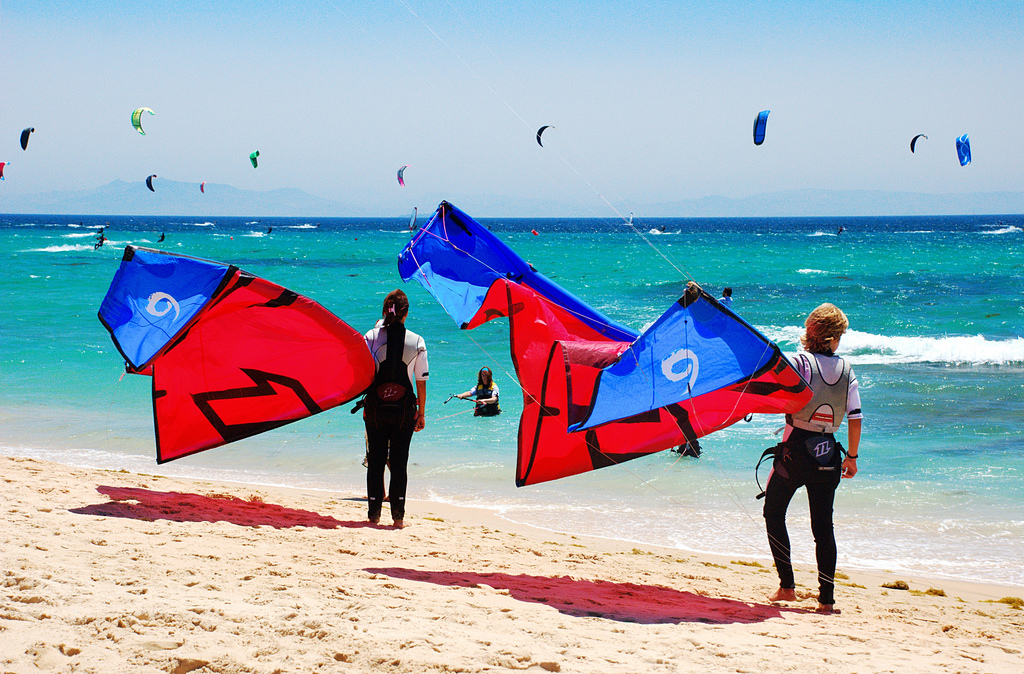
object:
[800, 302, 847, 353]
hair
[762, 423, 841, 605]
pants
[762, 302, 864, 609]
man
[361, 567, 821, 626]
shadow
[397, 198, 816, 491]
kite